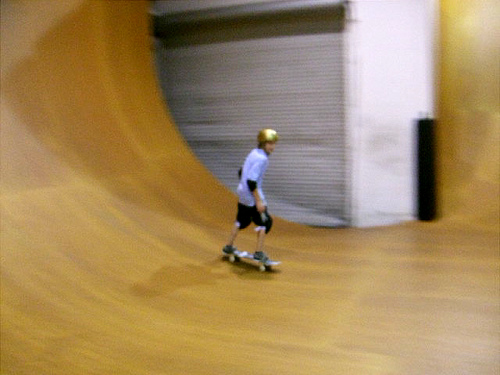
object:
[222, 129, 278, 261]
boy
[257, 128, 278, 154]
helmet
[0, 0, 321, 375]
ramp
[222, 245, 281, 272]
skateboard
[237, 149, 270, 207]
shirt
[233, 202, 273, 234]
shorts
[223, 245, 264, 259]
sneakers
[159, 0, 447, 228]
wall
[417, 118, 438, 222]
door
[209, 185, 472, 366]
surface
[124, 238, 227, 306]
shadow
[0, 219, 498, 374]
ground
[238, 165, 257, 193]
elbow sleeves